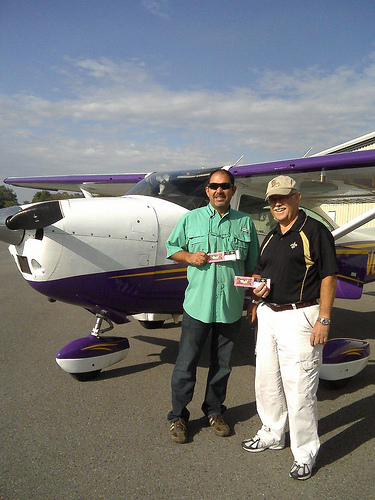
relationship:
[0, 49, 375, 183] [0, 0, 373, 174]
clouds in sky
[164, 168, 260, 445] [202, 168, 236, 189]
man with dark hair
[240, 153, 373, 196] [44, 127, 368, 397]
wing on a plane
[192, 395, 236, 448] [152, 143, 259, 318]
shoe of a man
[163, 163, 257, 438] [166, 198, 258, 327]
man wearing green shirt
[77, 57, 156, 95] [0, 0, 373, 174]
clouds in sky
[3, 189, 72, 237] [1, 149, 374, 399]
propeller on a plane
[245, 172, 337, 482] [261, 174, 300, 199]
man wearing a cap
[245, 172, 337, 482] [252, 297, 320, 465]
man wearing pants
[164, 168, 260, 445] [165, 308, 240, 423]
man wearing jeans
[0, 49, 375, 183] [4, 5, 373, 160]
clouds in sky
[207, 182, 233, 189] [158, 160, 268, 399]
glasses on man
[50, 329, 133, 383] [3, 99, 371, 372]
wheel of a plane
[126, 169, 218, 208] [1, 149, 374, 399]
window on a plane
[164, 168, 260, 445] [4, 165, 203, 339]
man standing in front of a plane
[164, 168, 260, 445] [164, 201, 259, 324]
man wearing green shirt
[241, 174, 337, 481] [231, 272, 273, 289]
man holding ticket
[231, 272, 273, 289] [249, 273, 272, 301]
ticket in hand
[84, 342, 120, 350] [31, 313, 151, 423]
marks are on wheel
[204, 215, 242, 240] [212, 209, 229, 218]
glasses arehanging from h neck